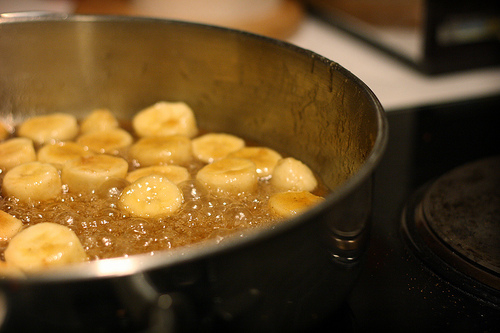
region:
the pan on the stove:
[0, 11, 385, 331]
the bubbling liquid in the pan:
[0, 105, 326, 264]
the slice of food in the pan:
[132, 99, 196, 136]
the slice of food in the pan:
[193, 132, 243, 162]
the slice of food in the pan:
[229, 147, 282, 179]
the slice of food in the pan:
[273, 156, 318, 191]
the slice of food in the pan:
[270, 189, 325, 217]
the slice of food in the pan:
[122, 179, 181, 216]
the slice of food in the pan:
[2, 223, 88, 267]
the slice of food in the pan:
[0, 160, 60, 200]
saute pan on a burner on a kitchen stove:
[0, 8, 386, 320]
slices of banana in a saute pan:
[0, 95, 327, 273]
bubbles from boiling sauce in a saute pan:
[77, 211, 229, 241]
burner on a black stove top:
[411, 153, 498, 275]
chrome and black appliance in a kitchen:
[302, 0, 490, 82]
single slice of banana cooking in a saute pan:
[132, 99, 198, 139]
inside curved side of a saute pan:
[1, 10, 320, 96]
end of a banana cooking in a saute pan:
[267, 158, 324, 195]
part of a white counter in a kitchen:
[292, 23, 483, 108]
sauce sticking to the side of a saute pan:
[225, 30, 367, 184]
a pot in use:
[0, 0, 406, 322]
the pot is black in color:
[0, 10, 391, 328]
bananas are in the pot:
[0, 100, 326, 266]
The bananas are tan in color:
[3, 100, 328, 260]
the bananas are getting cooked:
[3, 98, 326, 283]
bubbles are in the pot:
[13, 187, 293, 254]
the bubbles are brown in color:
[3, 188, 277, 250]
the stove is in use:
[116, 109, 496, 331]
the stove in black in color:
[146, 102, 490, 328]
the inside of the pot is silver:
[3, 8, 405, 322]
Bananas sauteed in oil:
[1, 82, 328, 264]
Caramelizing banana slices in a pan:
[2, 78, 353, 289]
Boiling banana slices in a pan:
[3, 74, 381, 322]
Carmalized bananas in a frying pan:
[7, 95, 290, 229]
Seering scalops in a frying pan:
[2, 91, 346, 281]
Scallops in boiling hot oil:
[2, 88, 339, 288]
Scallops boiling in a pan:
[5, 88, 320, 275]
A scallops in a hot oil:
[113, 170, 198, 226]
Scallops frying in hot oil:
[26, 114, 308, 253]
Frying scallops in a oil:
[21, 102, 348, 282]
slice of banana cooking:
[113, 179, 187, 218]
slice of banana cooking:
[15, 224, 83, 261]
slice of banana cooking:
[11, 165, 56, 195]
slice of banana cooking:
[203, 158, 254, 193]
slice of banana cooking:
[266, 190, 316, 215]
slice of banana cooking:
[197, 131, 239, 159]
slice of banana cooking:
[136, 103, 198, 129]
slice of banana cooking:
[18, 114, 68, 138]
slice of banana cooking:
[41, 142, 83, 159]